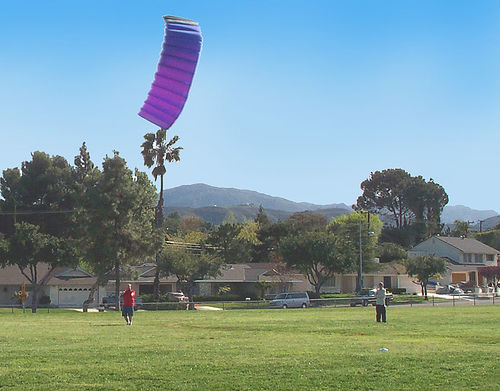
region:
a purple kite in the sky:
[129, 11, 210, 133]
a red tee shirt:
[116, 280, 138, 308]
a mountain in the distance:
[151, 171, 498, 226]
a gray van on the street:
[265, 286, 317, 316]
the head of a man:
[122, 277, 137, 291]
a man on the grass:
[116, 279, 142, 329]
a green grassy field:
[0, 296, 498, 390]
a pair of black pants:
[374, 302, 390, 322]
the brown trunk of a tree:
[27, 284, 44, 316]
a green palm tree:
[136, 128, 191, 180]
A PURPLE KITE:
[121, 16, 219, 136]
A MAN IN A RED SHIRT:
[109, 276, 160, 337]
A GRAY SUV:
[266, 285, 322, 312]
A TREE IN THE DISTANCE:
[347, 161, 458, 242]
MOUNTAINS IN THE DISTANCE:
[168, 168, 330, 213]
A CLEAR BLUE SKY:
[323, 50, 451, 124]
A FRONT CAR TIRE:
[279, 299, 293, 314]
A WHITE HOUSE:
[401, 231, 498, 280]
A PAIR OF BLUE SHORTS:
[116, 303, 146, 320]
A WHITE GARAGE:
[42, 283, 109, 313]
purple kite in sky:
[97, 14, 221, 186]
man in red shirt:
[101, 247, 185, 378]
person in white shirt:
[364, 248, 412, 358]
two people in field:
[21, 12, 425, 372]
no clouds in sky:
[11, 14, 498, 225]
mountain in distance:
[11, 137, 482, 325]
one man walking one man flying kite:
[87, 31, 445, 358]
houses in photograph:
[8, 200, 473, 325]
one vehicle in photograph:
[252, 270, 329, 337]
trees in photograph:
[1, 125, 465, 317]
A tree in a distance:
[280, 220, 346, 307]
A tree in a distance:
[332, 214, 385, 268]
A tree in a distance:
[405, 252, 444, 297]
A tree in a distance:
[373, 232, 407, 261]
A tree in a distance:
[352, 162, 408, 225]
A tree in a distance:
[405, 171, 432, 219]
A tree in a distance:
[159, 239, 222, 301]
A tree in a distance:
[195, 216, 245, 263]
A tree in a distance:
[79, 149, 163, 333]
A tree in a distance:
[137, 123, 176, 207]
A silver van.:
[265, 286, 312, 318]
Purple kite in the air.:
[140, 9, 202, 142]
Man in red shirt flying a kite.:
[110, 8, 198, 331]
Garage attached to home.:
[44, 277, 109, 314]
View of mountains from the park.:
[155, 151, 424, 320]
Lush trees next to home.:
[16, 149, 156, 277]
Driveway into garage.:
[195, 292, 220, 330]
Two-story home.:
[420, 219, 497, 296]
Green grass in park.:
[18, 276, 476, 387]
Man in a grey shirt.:
[366, 279, 398, 324]